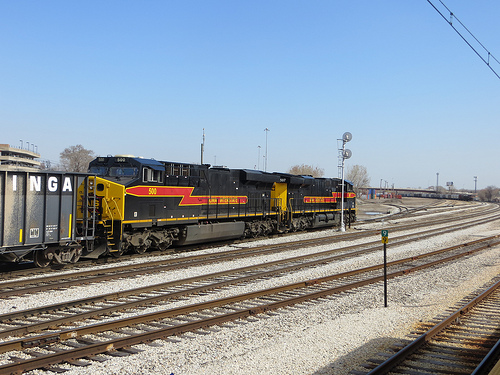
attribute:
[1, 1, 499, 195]
sky — blue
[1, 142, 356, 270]
train — black, yellow, red, parked, back, grey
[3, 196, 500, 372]
tracks — brown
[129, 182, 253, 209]
stripe — red, zig zag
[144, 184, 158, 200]
numbers — yellow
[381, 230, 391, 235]
sign — green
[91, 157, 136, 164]
lights — off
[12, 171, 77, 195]
letters — white, inga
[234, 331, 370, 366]
ground — rocky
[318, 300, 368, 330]
gravel — white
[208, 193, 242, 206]
letters — yellow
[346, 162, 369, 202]
tree — bare, green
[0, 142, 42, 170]
building — back